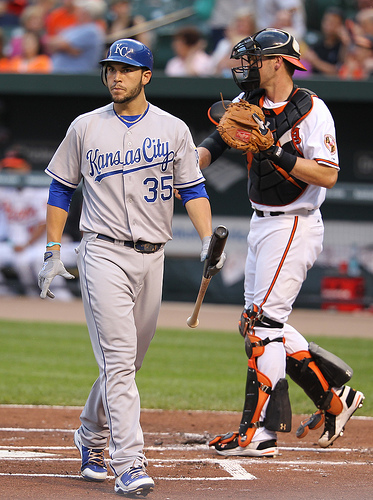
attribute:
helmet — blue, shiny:
[100, 38, 154, 83]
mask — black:
[231, 36, 262, 91]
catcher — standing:
[161, 26, 368, 462]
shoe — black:
[214, 430, 280, 458]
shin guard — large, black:
[233, 350, 273, 445]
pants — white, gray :
[241, 210, 329, 439]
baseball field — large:
[2, 292, 369, 499]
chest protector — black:
[229, 80, 324, 210]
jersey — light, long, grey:
[43, 99, 206, 243]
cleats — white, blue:
[71, 423, 157, 496]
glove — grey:
[33, 248, 75, 299]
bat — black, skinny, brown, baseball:
[185, 222, 229, 329]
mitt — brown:
[217, 98, 274, 156]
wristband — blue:
[43, 239, 64, 251]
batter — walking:
[37, 32, 235, 498]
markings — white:
[162, 427, 254, 489]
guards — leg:
[239, 303, 296, 468]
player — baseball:
[29, 35, 223, 496]